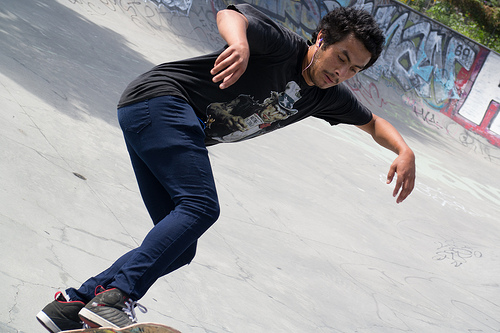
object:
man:
[38, 4, 416, 332]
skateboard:
[62, 322, 184, 331]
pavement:
[0, 0, 498, 332]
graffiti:
[427, 36, 476, 114]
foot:
[36, 286, 85, 332]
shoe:
[79, 289, 135, 332]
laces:
[122, 299, 146, 324]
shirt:
[118, 3, 371, 145]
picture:
[203, 79, 304, 144]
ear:
[315, 29, 327, 47]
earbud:
[317, 37, 324, 44]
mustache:
[324, 68, 339, 83]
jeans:
[66, 97, 219, 310]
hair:
[309, 6, 384, 72]